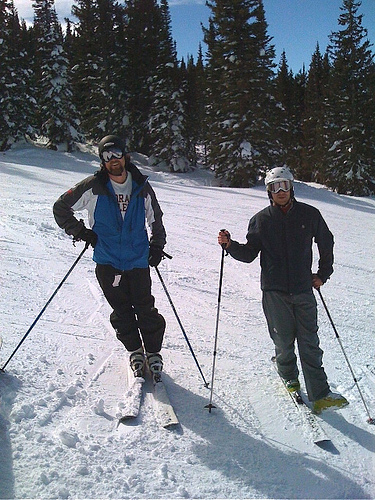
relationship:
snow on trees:
[157, 78, 186, 149] [11, 25, 372, 175]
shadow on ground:
[164, 384, 351, 498] [31, 173, 374, 490]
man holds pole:
[200, 151, 369, 430] [181, 250, 229, 421]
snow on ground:
[173, 194, 212, 249] [31, 173, 374, 490]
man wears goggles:
[200, 151, 369, 430] [251, 173, 303, 194]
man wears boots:
[200, 151, 369, 430] [274, 365, 349, 416]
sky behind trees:
[267, 1, 354, 64] [11, 25, 372, 175]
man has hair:
[42, 141, 183, 409] [110, 162, 124, 174]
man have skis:
[217, 166, 348, 415] [111, 335, 344, 454]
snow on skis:
[157, 78, 186, 149] [111, 335, 344, 454]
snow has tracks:
[173, 194, 212, 249] [35, 373, 163, 484]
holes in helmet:
[272, 163, 282, 179] [255, 154, 292, 191]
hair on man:
[110, 162, 124, 174] [42, 141, 183, 409]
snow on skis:
[173, 194, 212, 249] [111, 335, 344, 454]